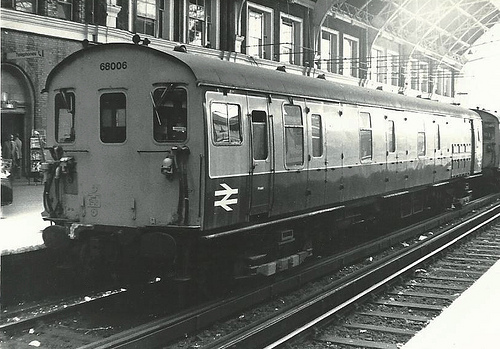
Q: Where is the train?
A: On the tracks.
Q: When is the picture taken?
A: Daytime.